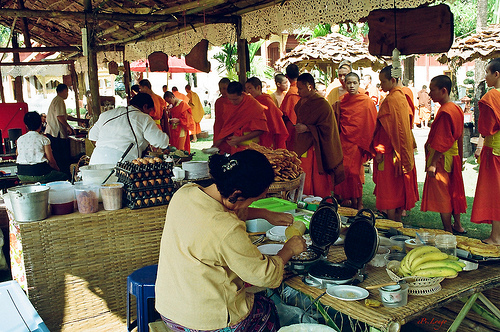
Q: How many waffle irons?
A: Two.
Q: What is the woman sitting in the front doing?
A: Making a waffle.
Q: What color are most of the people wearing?
A: Orange.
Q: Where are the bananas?
A: Basket on table.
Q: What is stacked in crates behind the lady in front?
A: Eggs.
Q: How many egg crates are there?
A: Five.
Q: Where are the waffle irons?
A: On the table.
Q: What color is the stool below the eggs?
A: Blue.